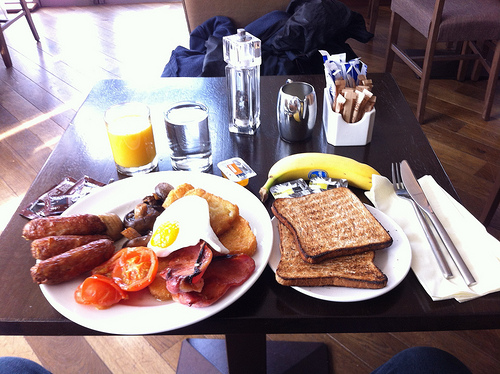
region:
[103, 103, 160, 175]
Glass of orange juice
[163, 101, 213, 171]
Glass of water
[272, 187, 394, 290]
Two pieces of toast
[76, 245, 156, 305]
Two pieces of tomato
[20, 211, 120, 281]
Three sausage links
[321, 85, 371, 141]
White container with sugar packets in it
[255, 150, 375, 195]
Banana on a table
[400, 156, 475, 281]
Knife on a napkin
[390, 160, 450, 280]
Fork on a napkin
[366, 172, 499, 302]
Two napkins under some silverware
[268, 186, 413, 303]
brown toast on white plate.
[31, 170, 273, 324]
different breakfast foods on white plate.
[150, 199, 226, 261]
cooked egg with yellow yolk.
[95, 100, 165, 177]
glass of orange juice next to water.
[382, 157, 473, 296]
knife and fork on white napkin.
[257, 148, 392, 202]
yellow banana next to plate of toast.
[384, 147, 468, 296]
utensils are silver on napkin.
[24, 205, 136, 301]
three sausages on white plate.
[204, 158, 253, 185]
small container of jelly on table.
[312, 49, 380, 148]
dish with condiments on table.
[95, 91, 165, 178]
glass of orange juice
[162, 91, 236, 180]
glass of water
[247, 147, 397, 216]
yellow ripe banana with brown spots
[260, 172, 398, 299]
two slices of toasted bread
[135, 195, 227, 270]
one fried egg sunny side up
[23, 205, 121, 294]
three links of sausage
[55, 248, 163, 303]
red ripe tomatoes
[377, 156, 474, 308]
silver fork and knife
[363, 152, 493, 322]
white paper napkin folded in half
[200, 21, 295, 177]
clear salt and pepper grinder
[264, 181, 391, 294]
two slices of toast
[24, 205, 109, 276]
sausages on plate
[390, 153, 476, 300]
knife and for on napkin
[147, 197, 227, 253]
egg on a plate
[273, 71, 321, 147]
silver pitcher on table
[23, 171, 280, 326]
plate filled with breakfast meal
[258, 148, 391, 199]
banana above the toast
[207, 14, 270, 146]
glass pepper mill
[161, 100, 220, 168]
glass of water on table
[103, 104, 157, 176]
A glass of orange juice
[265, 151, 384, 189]
An unpeeled banana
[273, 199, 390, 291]
two slices of plain toast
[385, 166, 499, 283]
a fork and a knife to eat with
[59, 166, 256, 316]
A plate full of breakfast foods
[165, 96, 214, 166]
a glass of water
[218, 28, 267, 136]
a pepper mill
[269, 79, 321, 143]
a coffee creamer urn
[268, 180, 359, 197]
various jams and jellies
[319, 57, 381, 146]
sugar and artificial sweetener packets